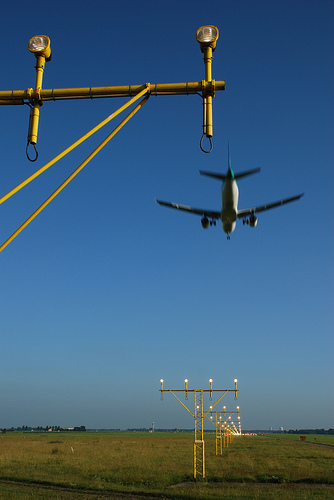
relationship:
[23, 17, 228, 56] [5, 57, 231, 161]
lights attached to towers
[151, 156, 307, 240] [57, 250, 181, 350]
airplane flying in sky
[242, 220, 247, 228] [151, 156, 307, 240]
wheel of airplane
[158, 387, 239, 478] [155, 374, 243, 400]
pole with lights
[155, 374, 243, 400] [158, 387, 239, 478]
lights attached to pole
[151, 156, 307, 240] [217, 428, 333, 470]
airplane coming in for landing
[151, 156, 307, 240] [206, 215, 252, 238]
airplane with wheels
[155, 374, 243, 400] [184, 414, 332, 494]
lights on runway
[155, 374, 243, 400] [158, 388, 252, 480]
lights attached to bars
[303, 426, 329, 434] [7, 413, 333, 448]
trees in background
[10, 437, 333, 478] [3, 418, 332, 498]
field at airport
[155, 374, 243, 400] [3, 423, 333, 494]
lights at airport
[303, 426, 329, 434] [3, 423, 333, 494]
trees near airport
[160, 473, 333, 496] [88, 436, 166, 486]
path through field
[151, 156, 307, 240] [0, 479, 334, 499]
airplane approaching path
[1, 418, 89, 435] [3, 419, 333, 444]
buildings in background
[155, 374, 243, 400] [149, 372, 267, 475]
lights in distance